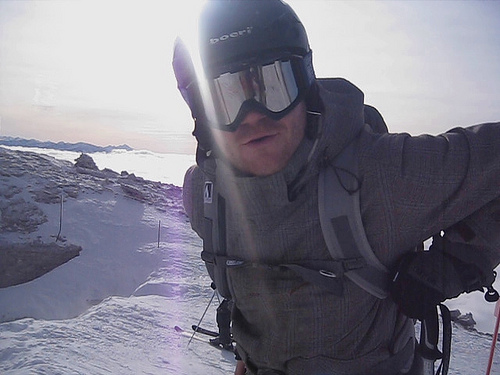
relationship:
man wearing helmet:
[166, 2, 499, 375] [166, 5, 327, 116]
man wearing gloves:
[166, 2, 499, 375] [397, 264, 450, 320]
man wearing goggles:
[166, 2, 499, 375] [194, 64, 307, 119]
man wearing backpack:
[166, 2, 499, 375] [322, 141, 453, 324]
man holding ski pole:
[166, 2, 499, 375] [192, 288, 218, 348]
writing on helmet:
[210, 28, 258, 46] [166, 5, 327, 116]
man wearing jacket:
[166, 2, 499, 375] [192, 140, 491, 375]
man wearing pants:
[166, 2, 499, 375] [208, 292, 241, 360]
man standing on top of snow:
[166, 2, 499, 375] [10, 146, 278, 374]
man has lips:
[166, 2, 499, 375] [242, 135, 278, 146]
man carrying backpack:
[166, 2, 499, 375] [322, 141, 453, 324]